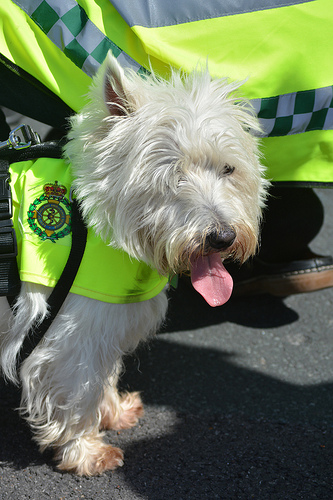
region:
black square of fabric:
[258, 97, 276, 115]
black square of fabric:
[307, 107, 326, 132]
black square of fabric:
[90, 37, 119, 64]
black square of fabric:
[62, 37, 88, 70]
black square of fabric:
[28, 2, 55, 31]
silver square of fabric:
[313, 87, 332, 109]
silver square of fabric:
[75, 23, 101, 52]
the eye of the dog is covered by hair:
[143, 155, 202, 196]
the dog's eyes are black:
[213, 150, 240, 185]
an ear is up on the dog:
[78, 43, 153, 136]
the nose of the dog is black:
[203, 219, 238, 252]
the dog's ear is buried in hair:
[198, 61, 252, 120]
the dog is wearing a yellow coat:
[3, 148, 176, 305]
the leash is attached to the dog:
[2, 116, 68, 166]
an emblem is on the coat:
[26, 172, 77, 246]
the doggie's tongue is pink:
[180, 226, 242, 317]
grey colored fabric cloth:
[312, 87, 331, 109]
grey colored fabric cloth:
[288, 114, 309, 134]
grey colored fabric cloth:
[251, 120, 271, 137]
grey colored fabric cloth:
[241, 100, 259, 118]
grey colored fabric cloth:
[114, 51, 138, 72]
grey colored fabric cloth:
[73, 22, 103, 53]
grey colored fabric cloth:
[46, 2, 76, 18]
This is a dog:
[4, 55, 267, 489]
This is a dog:
[27, 54, 268, 496]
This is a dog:
[26, 55, 242, 493]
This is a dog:
[10, 38, 298, 492]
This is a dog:
[23, 44, 308, 498]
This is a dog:
[26, 31, 301, 498]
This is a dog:
[21, 34, 286, 498]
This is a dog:
[4, 34, 289, 495]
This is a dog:
[29, 34, 281, 498]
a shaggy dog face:
[52, 57, 304, 369]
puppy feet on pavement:
[7, 356, 211, 484]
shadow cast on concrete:
[133, 391, 330, 490]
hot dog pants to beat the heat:
[166, 221, 257, 309]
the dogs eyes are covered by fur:
[122, 137, 276, 195]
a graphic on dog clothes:
[23, 170, 90, 249]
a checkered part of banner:
[39, 10, 127, 68]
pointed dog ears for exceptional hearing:
[90, 48, 166, 148]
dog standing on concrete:
[0, 47, 268, 479]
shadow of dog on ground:
[86, 322, 329, 499]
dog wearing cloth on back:
[2, 142, 170, 303]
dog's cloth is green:
[6, 149, 175, 308]